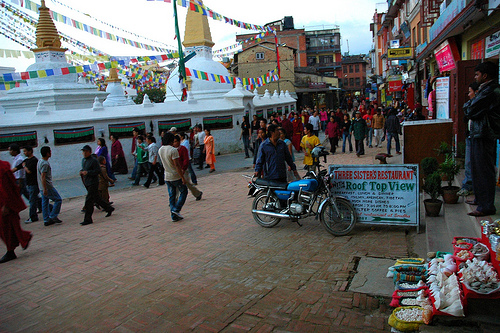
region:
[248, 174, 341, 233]
this is a motorcycle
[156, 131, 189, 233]
this is a man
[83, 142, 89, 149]
this is a cap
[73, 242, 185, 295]
this is the ground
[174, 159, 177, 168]
the man has a light skin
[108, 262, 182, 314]
the ground is stoney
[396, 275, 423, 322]
these are grains in small bags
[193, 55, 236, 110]
this is a building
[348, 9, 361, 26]
this is the sky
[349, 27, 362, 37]
the sky is blue in color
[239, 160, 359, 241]
Motorcycle painted blue.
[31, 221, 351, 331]
Brick walkway.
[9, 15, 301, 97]
Colorful banners hung above the street.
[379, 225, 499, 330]
Goods on display for sale.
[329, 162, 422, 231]
Sign advertising a Restaurant.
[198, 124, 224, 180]
Woman wearing an orange outfit.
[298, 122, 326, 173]
Boy wearing a yellow shirt.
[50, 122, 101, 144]
Small rectangular window.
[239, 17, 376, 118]
Tall brick buildings.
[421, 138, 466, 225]
two plants in pots sitting on steps.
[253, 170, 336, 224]
this is a motorcycle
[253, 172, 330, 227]
the motorcycle is blue in coor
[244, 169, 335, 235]
the motorcycle is parked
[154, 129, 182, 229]
the men are walking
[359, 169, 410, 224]
the poster is white in color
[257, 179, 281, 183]
the seat is black in coor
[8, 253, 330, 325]
the floor is old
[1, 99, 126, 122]
the building is white in color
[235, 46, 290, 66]
the building is tall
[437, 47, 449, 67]
the poster is red in color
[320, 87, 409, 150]
crowd of people on walkway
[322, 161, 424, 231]
restaurant sign on walkway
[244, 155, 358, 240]
motorbike parked next to sign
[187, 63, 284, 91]
colored squares on rope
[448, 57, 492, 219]
people standing in doorway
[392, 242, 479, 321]
baskets of items on stairs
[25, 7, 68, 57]
yellow steeple on dome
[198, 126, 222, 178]
woman dressed in orange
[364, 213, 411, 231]
green arrow on sign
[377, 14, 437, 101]
multi story buildings along walkway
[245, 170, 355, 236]
this is a motor cycyle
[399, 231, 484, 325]
this is grocery items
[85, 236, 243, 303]
this is the road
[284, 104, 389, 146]
these are people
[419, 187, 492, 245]
these are staircase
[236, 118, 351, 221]
the man is standing next to a motorcycle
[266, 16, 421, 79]
this is a building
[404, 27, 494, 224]
these are shops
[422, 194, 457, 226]
this is a flower vessels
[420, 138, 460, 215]
these are flowers